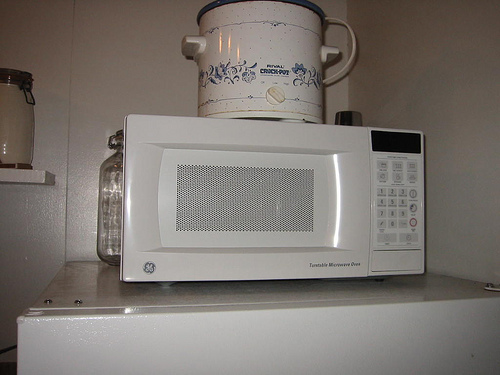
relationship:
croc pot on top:
[178, 0, 364, 122] [125, 90, 459, 131]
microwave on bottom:
[119, 113, 434, 279] [95, 277, 463, 303]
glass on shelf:
[1, 65, 35, 170] [1, 162, 55, 183]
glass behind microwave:
[98, 121, 123, 272] [119, 113, 434, 279]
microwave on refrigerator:
[119, 113, 434, 279] [16, 265, 494, 362]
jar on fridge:
[98, 121, 123, 272] [16, 265, 494, 362]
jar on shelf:
[1, 65, 35, 170] [1, 162, 55, 183]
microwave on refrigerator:
[118, 113, 433, 286] [16, 265, 494, 362]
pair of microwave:
[126, 1, 430, 279] [118, 113, 433, 286]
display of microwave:
[370, 132, 424, 157] [119, 113, 434, 279]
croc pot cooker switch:
[178, 0, 364, 122] [262, 86, 288, 108]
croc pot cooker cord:
[178, 0, 364, 122] [322, 16, 358, 85]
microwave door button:
[119, 113, 434, 279] [372, 250, 423, 272]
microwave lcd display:
[119, 113, 434, 279] [370, 132, 424, 157]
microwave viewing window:
[119, 113, 434, 279] [175, 166, 317, 232]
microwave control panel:
[119, 113, 434, 279] [373, 151, 424, 249]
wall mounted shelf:
[1, 4, 499, 301] [1, 162, 55, 183]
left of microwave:
[34, 104, 121, 306] [119, 113, 434, 279]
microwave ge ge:
[119, 113, 434, 279] [142, 260, 157, 275]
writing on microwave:
[307, 260, 364, 269] [119, 113, 434, 279]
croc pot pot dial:
[178, 0, 364, 122] [262, 86, 288, 108]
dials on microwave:
[373, 151, 424, 249] [119, 113, 434, 279]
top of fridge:
[16, 261, 498, 304] [16, 265, 494, 362]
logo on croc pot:
[258, 63, 294, 77] [178, 0, 364, 122]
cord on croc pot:
[322, 16, 358, 85] [178, 0, 364, 122]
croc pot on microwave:
[178, 0, 364, 122] [119, 113, 434, 279]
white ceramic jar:
[2, 84, 33, 165] [1, 65, 35, 170]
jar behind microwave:
[98, 121, 123, 272] [119, 113, 434, 279]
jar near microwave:
[98, 121, 123, 272] [119, 113, 434, 279]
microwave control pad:
[119, 113, 434, 279] [373, 151, 424, 249]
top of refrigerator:
[16, 261, 498, 304] [16, 265, 494, 362]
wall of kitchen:
[1, 4, 499, 301] [3, 3, 495, 374]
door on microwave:
[126, 116, 372, 278] [119, 113, 434, 279]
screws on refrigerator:
[37, 294, 92, 307] [16, 265, 494, 362]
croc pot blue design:
[178, 0, 364, 122] [201, 64, 322, 96]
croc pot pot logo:
[178, 0, 364, 122] [258, 63, 294, 77]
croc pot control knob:
[178, 0, 364, 122] [262, 86, 288, 108]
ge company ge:
[144, 260, 158, 274] [142, 260, 157, 275]